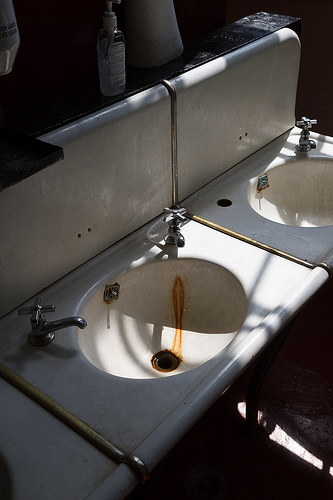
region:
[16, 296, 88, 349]
vintage metal sink faucet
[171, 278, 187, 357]
long hard water stain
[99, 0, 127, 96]
bottle of hand soap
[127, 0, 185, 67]
roll of paper towels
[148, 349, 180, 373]
corroded sink drain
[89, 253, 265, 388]
porcelain white sink bowl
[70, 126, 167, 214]
white sink back splash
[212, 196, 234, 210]
hole for sink faucet assembly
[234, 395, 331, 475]
sunlight shining onto floor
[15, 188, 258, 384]
double faucet sink bowl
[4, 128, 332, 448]
A double bowl sink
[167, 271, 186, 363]
Rust stain in the sink on the left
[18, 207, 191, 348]
Chrome fitting on the facets of the sink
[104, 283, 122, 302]
Overflow on the sink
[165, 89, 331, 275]
Brass piping between the sinks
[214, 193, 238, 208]
Facet missing on the sink on the right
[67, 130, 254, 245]
Four drilled holes in the backsplash board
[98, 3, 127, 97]
Liquid hand soap sitting on the top of the sinks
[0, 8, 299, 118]
Black board for sitting products on attached to the sinks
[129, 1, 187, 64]
A roll of paper towels sitting on the board above the sink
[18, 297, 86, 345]
a sink faucet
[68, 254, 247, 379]
a stained sink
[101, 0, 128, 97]
a bottle of soap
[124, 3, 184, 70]
a roll of paper towels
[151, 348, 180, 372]
a sink drain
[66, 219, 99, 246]
two holes in porcelain wall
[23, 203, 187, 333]
two sink faucets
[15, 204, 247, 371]
faucets and porcelain sink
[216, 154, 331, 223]
missing faucet hole on white sink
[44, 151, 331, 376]
two dirty white sinks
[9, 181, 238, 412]
A beige colored sink on left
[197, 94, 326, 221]
A beige colored sink on right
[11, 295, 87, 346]
A chrome faucet on left side of sink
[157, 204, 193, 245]
A chrome faucet on right of sink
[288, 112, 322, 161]
A chrome faucet on right side of other sink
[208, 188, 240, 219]
A hole on left of other sink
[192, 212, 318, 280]
A metal strip between sinks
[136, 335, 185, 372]
Rusty drain in the sink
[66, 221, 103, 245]
Two holes in the sink back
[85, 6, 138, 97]
Hand soap of sanitizer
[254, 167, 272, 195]
rust coroded green metal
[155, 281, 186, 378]
strong rust stain in sink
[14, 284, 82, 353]
silver sink water handle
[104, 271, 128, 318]
coroded metal sink grate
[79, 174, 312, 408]
2 white sink bowls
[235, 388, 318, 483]
sunlit on the ground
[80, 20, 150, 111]
some kind of bathroom item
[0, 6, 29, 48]
white object with black lettering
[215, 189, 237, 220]
small black hole in sink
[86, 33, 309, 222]
large white sink backdrop